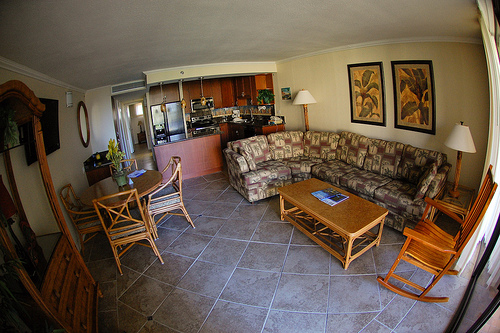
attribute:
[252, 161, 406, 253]
table — wooden, wood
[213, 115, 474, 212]
couch — sofa, empty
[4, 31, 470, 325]
room — picture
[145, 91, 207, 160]
refrigerator — metal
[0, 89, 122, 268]
wall — white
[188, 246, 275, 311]
floor — tiled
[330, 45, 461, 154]
paintings — hanged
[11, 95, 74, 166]
tv — off, black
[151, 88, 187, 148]
kitchen — steel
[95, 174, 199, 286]
chair — bamboo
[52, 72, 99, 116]
air — white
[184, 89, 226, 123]
microwave — steel